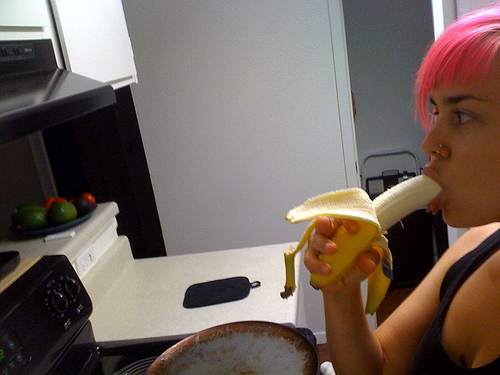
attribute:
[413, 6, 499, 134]
hair — pink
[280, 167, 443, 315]
banana — yellow, ripe, peeled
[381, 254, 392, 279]
sticker — blue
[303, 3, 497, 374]
girl — standing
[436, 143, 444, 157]
ring — silver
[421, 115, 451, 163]
nose — pierced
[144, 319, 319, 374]
plate — dirty, rusted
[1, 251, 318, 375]
oven — black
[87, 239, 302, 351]
counter — white, whtie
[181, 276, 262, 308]
potholder — square, black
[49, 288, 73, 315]
knob — black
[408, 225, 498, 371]
shirt — black